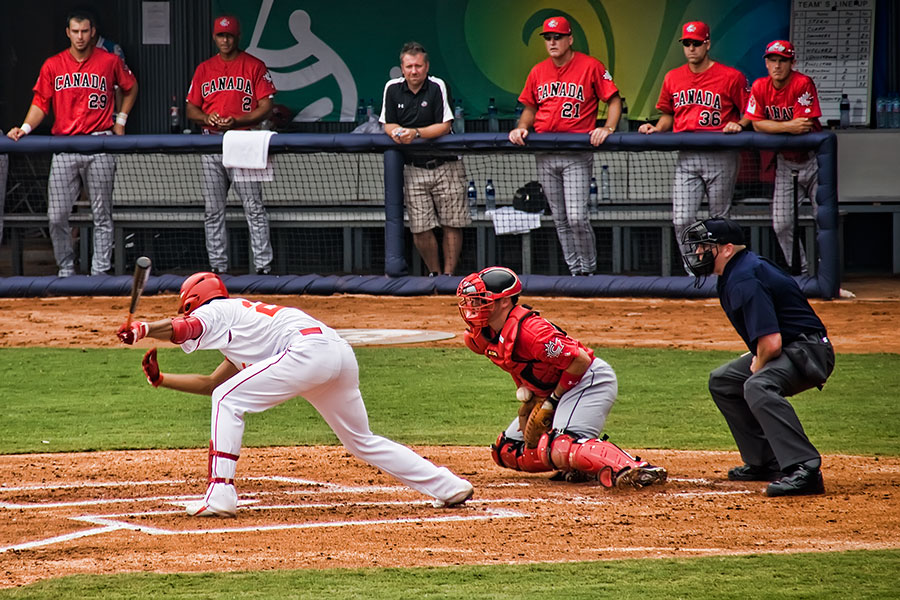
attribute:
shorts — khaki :
[388, 157, 471, 235]